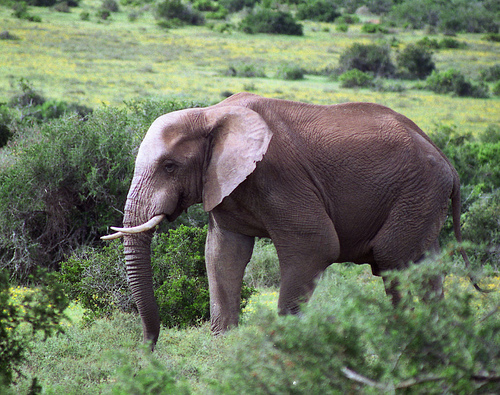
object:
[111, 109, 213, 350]
head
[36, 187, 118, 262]
branch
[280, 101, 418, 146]
back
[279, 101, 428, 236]
skin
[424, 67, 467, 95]
bushes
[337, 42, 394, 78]
bushes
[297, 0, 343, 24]
bushes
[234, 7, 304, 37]
bushes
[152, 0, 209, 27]
bushes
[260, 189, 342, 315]
leg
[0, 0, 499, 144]
field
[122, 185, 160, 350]
elephant trunk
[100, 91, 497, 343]
elephant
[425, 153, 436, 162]
bump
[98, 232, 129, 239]
right tusk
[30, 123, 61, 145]
leaves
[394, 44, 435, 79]
tree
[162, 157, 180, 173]
eye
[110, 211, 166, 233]
tusk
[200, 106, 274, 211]
ear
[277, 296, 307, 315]
ankle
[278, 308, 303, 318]
feet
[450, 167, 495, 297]
tail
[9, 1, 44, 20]
brush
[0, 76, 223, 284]
brushes